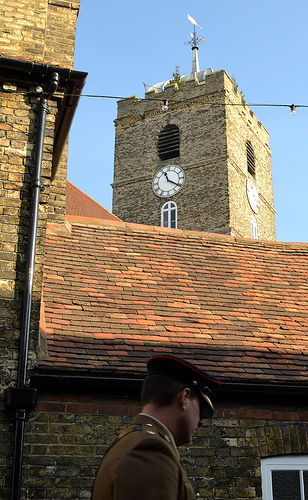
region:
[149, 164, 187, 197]
a white clock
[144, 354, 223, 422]
red, black, and gold hat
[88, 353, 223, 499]
man wearing a uniform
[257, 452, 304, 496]
the corner of a window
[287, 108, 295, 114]
a clear lightbulb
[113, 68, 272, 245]
a tall brick tower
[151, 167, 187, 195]
Clock on a brown tower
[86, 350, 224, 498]
Guy in front of brick building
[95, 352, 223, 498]
Guy in front of brown building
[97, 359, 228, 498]
Guy in front of brown brick building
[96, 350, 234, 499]
Soldier in front of building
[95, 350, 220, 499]
Soldier in front of brick building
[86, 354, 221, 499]
Soldier in front of brown brick building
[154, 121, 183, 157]
Window of brown brick tower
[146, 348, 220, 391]
Soldier's military issued hat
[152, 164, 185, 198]
More visible white clock face.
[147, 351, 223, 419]
Black and red military hat.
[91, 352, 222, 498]
Brown haired man in brown uniform.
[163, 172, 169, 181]
Black hour hand on a more visible clock.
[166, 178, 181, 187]
Black minute hand on a more visible clock.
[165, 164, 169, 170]
Roman numeral XII on the top of a more visible clock.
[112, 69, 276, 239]
A brown brick clock tower.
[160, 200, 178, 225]
A window on a building.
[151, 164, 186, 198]
a clock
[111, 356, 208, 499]
a man standing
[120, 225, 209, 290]
bricks on the roof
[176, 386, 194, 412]
mans ear